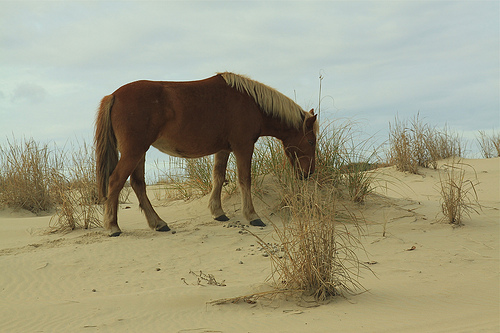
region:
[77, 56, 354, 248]
Dark brown horse in samd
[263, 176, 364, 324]
Grass growing from the sand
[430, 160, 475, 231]
Grass growing from the sand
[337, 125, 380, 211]
Grass growing from the sand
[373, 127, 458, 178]
Grass growing from the sand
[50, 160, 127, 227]
Grass growing from the sand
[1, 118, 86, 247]
Grass growing from the sand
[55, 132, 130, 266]
Grass growing from the sand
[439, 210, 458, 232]
part of a hill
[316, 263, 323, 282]
part of a grass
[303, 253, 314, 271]
part of a bush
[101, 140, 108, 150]
tail of a horse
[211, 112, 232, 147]
body of a horse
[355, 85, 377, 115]
part of the sky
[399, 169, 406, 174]
part of a hill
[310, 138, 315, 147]
head of a cow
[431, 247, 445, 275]
edge of a sand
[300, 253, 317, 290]
edge of a bush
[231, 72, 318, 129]
Horse has blonde mane.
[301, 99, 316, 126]
Horse has brown ears.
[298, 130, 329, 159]
Horse has dark eye.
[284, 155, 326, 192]
Horse has brown nose.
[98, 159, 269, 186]
Horse has brown legs.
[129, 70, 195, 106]
Horse has brown back.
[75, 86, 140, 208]
Horse has light brown tail.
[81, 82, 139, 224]
Horse has long tail.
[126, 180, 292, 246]
Horse standing on the sand.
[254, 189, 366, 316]
Brown weeds sticking out of sand.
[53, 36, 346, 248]
a horse is grazing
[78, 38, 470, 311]
the horse is standing on sand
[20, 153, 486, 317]
the ground is covered in sand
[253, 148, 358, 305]
some dry grass is on the ground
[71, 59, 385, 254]
the horse is brown in color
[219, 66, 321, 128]
the horses mane is light brown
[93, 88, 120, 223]
the horses tail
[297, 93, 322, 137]
the horses ears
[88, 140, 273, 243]
the horses four legs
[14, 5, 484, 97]
the sky is full of white clouds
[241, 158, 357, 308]
tall bunches of dry grass for the horse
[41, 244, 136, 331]
sand on the ground surrounded by grass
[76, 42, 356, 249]
a beautiful brown horse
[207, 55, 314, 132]
the horse's mane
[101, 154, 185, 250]
the horse's back legs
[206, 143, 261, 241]
the horse's front legs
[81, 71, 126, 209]
the horse's tail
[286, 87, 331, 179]
the horse is eating grass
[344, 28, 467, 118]
a cloudy blue sky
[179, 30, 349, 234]
half of the horse eating grass